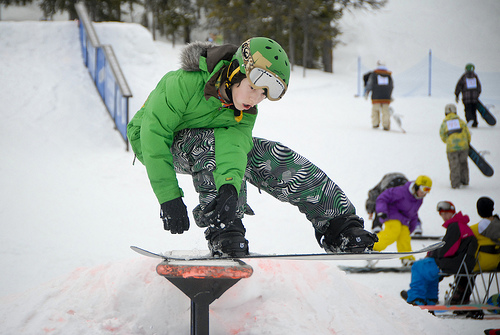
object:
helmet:
[228, 37, 294, 101]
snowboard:
[126, 238, 450, 266]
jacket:
[437, 114, 472, 154]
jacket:
[368, 184, 424, 232]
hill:
[0, 21, 184, 261]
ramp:
[71, 0, 132, 148]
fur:
[181, 42, 202, 72]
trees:
[309, 1, 353, 79]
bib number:
[446, 118, 463, 134]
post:
[185, 300, 213, 334]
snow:
[1, 1, 498, 334]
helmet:
[412, 174, 433, 197]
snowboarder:
[121, 35, 381, 255]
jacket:
[119, 56, 264, 203]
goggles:
[237, 39, 287, 101]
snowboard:
[461, 143, 499, 177]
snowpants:
[370, 219, 416, 263]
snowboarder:
[366, 175, 435, 269]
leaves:
[250, 1, 272, 13]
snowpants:
[154, 128, 364, 228]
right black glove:
[157, 194, 193, 235]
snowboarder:
[364, 57, 399, 132]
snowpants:
[371, 101, 395, 132]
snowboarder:
[437, 101, 471, 190]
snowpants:
[446, 148, 472, 189]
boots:
[203, 214, 254, 258]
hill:
[354, 52, 497, 189]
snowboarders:
[454, 63, 483, 129]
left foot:
[318, 211, 379, 254]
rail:
[156, 249, 256, 334]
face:
[236, 77, 264, 111]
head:
[226, 35, 291, 111]